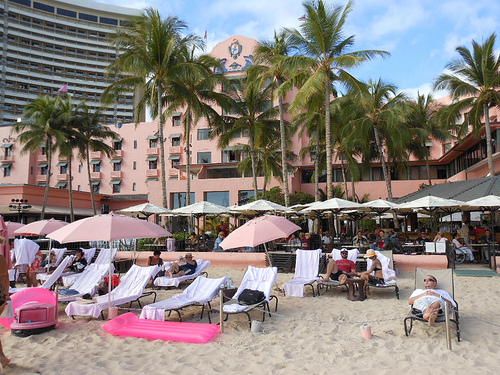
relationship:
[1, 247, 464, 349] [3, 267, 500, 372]
lounge chairs are on sand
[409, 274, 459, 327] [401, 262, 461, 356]
man reclining in lounge chair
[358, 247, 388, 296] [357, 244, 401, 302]
woman sitting on lounge chair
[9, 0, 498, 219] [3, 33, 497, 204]
palm trees are obscuring building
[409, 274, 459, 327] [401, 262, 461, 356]
man laying on lounge chair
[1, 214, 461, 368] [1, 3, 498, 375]
people are on beach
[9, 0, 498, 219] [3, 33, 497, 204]
palm trees are in front of building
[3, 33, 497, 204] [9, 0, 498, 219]
building behind palm trees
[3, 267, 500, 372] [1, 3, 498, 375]
sand on beach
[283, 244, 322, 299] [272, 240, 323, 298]
beach towel on chair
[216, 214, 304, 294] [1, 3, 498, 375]
umbrella on beach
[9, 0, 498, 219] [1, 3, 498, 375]
palm trees are by beach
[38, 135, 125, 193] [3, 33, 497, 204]
windows are on building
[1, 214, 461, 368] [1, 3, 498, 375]
people are relaxing on beach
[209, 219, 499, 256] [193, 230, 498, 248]
people are at tables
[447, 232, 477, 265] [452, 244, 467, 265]
person in wheelchair